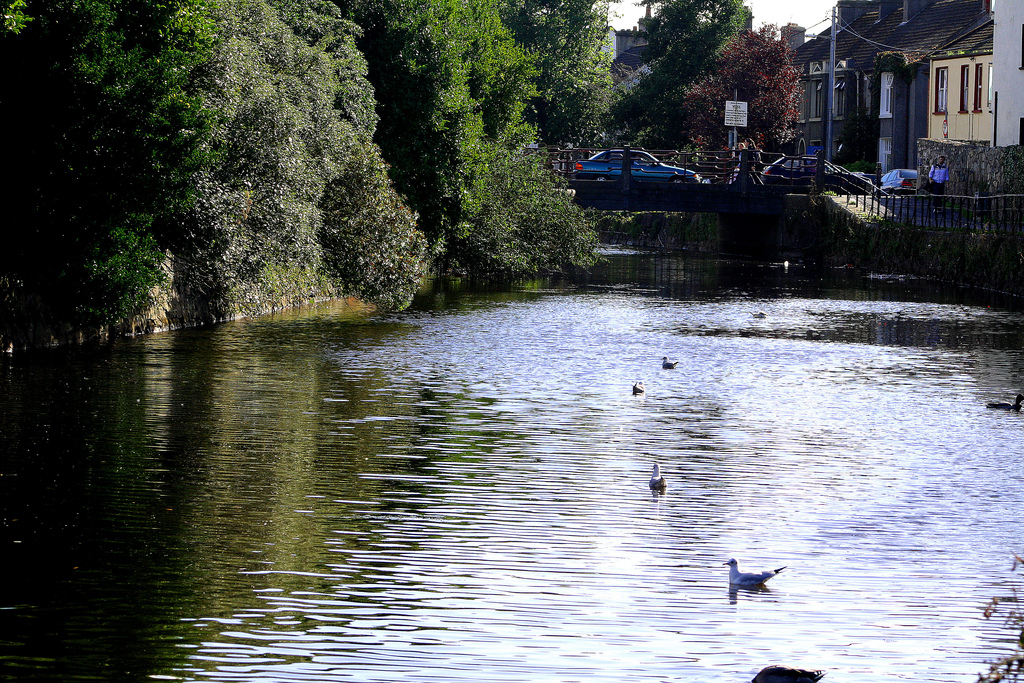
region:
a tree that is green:
[73, 75, 184, 183]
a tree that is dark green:
[396, 40, 534, 221]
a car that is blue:
[563, 130, 699, 194]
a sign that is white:
[701, 92, 752, 135]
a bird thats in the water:
[711, 543, 787, 597]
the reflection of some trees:
[184, 326, 407, 542]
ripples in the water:
[437, 598, 486, 647]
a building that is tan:
[916, 35, 993, 153]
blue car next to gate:
[562, 140, 708, 186]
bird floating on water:
[713, 549, 796, 594]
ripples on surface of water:
[369, 433, 461, 504]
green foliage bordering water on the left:
[3, 1, 618, 337]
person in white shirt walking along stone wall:
[922, 148, 955, 216]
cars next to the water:
[555, 69, 919, 247]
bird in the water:
[656, 509, 816, 628]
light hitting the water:
[427, 410, 636, 589]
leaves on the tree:
[357, 29, 561, 261]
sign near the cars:
[702, 64, 782, 134]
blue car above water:
[539, 111, 726, 210]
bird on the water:
[612, 383, 654, 406]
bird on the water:
[645, 356, 688, 380]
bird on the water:
[728, 306, 773, 325]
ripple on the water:
[492, 499, 570, 539]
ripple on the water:
[814, 360, 916, 396]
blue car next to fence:
[565, 142, 702, 182]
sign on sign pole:
[717, 82, 756, 150]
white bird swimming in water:
[713, 550, 796, 595]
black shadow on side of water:
[0, 297, 545, 674]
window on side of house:
[926, 60, 956, 119]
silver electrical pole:
[815, 7, 853, 164]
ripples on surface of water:
[442, 407, 569, 487]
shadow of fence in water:
[597, 244, 725, 295]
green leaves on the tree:
[449, 158, 487, 188]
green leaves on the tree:
[467, 261, 540, 299]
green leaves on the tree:
[448, 50, 526, 159]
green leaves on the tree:
[318, 125, 408, 215]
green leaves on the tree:
[129, 164, 194, 250]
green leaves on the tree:
[154, 84, 186, 145]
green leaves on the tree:
[79, 53, 136, 146]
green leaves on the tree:
[158, 24, 198, 81]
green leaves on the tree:
[299, 79, 370, 168]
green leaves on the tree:
[195, 176, 252, 260]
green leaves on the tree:
[489, 70, 509, 140]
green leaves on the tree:
[553, 239, 579, 285]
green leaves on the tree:
[441, 24, 489, 92]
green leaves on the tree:
[449, 173, 544, 254]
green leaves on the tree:
[370, 35, 447, 140]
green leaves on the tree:
[300, 202, 390, 313]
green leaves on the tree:
[303, 15, 396, 127]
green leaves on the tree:
[128, 173, 171, 282]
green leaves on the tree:
[54, 9, 211, 206]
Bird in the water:
[713, 548, 799, 612]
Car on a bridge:
[572, 144, 706, 190]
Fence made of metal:
[550, 143, 816, 195]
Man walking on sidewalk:
[920, 149, 953, 207]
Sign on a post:
[713, 86, 762, 143]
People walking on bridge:
[710, 130, 777, 185]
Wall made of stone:
[912, 135, 1020, 205]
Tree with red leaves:
[678, 27, 803, 148]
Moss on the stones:
[797, 212, 998, 301]